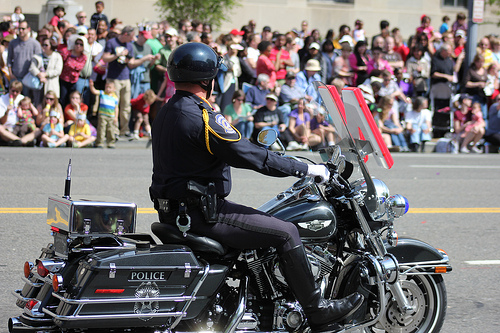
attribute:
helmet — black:
[166, 39, 223, 92]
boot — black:
[282, 242, 362, 328]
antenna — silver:
[67, 20, 94, 201]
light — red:
[36, 259, 49, 278]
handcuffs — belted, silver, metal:
[176, 207, 196, 241]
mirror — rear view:
[254, 128, 278, 146]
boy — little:
[69, 112, 96, 148]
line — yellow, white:
[3, 195, 500, 219]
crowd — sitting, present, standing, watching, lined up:
[0, 3, 500, 146]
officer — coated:
[147, 39, 365, 328]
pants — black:
[164, 197, 306, 251]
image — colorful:
[1, 2, 489, 328]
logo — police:
[301, 218, 333, 231]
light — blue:
[394, 198, 411, 219]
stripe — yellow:
[1, 197, 495, 227]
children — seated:
[3, 81, 146, 148]